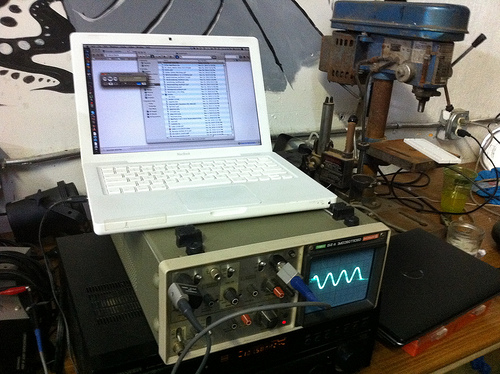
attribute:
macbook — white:
[52, 39, 350, 240]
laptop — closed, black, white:
[373, 206, 499, 335]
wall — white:
[6, 4, 347, 137]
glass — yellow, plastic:
[442, 156, 482, 221]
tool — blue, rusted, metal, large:
[317, 10, 465, 186]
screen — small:
[303, 255, 377, 310]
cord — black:
[31, 191, 92, 268]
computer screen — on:
[82, 46, 266, 145]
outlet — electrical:
[434, 100, 476, 152]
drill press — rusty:
[363, 68, 399, 177]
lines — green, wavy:
[312, 265, 367, 293]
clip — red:
[3, 277, 34, 296]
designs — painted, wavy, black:
[7, 7, 305, 79]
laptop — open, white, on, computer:
[51, 26, 346, 234]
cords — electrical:
[454, 113, 499, 188]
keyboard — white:
[97, 158, 297, 196]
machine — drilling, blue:
[332, 7, 487, 58]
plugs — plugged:
[351, 167, 453, 212]